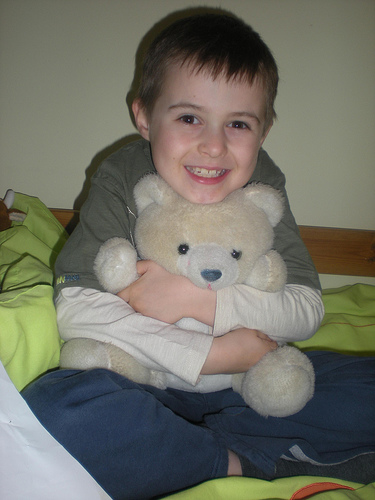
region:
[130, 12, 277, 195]
A child is smiling.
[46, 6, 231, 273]
The left side is casting a shadow on the wall.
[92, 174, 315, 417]
A child is holding a teddy bear.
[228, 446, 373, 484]
A foot in a gray sock is under a blue cover.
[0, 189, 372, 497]
The sheet is green with a orange edge.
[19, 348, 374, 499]
The The boy is wearing blue pants.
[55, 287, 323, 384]
The sleeves are white.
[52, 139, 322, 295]
The boy is wearing a gray shirt.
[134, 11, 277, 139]
The boy has brown hair.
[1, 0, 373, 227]
The wall is white.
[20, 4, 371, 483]
little boy holding teddy bear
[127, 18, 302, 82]
the boy's brown hair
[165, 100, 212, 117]
the boy's right eyebrow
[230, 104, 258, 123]
the boy's left eyebrow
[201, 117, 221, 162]
the little boy's nose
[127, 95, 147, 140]
the boy's right ear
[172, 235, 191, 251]
the teddy bear's right eye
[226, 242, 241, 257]
the bear's left eye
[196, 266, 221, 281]
the bear's black nose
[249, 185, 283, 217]
the white bear's left ear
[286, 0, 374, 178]
white wall for room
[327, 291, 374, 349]
lime green blanket for warmth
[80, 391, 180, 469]
sweat pants for warmth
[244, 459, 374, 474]
black socks for feet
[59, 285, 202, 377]
white long sleeve shirt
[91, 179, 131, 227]
gray tee shirt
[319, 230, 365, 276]
headboard from of bed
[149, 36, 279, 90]
blonde hair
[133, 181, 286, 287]
white teddy bear for joy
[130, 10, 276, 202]
young caucasian male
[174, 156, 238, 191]
boy with a smile on its face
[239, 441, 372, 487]
boy wearing black socks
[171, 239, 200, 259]
teddy bear with black eyes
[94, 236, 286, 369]
boy hugging a bear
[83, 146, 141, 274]
boy wearing a gray shirt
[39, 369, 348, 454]
boy wearing blue pants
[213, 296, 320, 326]
boy wearing a shirt with white sleeves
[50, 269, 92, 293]
logo on shirt sleeves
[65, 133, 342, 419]
boy sitting on a bed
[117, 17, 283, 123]
boy with brown hair